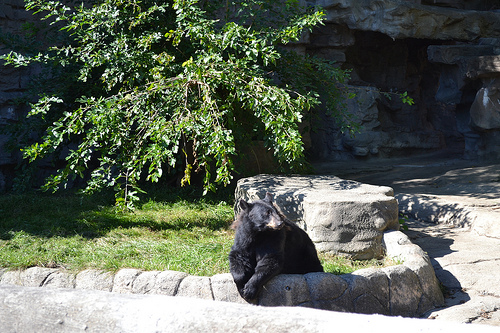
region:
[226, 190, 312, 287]
this is a bear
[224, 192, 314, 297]
the bear is sitted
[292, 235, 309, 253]
the fur is black in color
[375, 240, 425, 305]
this is a stony fence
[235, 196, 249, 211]
this is the ear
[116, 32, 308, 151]
the tree is branchy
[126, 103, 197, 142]
the leaves are green in color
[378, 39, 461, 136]
this is a cave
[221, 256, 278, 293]
these are the fore limbs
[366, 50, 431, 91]
the cave is dark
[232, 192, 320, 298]
black bear in grass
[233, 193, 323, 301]
black bear on rocks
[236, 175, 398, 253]
grey rock boulder on ground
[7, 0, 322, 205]
tree with green leaves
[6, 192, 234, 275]
grass next to tree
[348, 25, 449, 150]
cave inside rock wall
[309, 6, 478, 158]
stacked boulders on ground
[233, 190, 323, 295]
bear sitting on ground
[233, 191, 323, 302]
bear relaxing in sun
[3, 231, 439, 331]
concrete barrier on ground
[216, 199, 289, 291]
Bear leaning over a rock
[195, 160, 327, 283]
Black bear standing on rock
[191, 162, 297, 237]
Bear with his head turned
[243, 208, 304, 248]
Bear with brown and black nose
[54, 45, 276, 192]
Tree over a rock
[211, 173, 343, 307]
Bear hanging over a rock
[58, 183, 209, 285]
Patch of grass surrounded by stone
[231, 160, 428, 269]
Platform in the grass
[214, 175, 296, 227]
Bear with it's ears perked up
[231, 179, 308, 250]
Bear looking forward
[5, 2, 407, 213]
green leaves of bush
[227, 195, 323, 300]
bear leaning on wall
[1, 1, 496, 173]
wall of zoo enclosure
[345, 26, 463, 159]
opening in rock wall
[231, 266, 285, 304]
two front black paws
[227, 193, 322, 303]
black bear looking right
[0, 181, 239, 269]
green grass with shadows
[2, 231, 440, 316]
man made stone wall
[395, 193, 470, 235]
shadow of leaves on ground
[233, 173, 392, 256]
round flat top stone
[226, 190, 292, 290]
this is a bear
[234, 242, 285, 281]
the bear is black in color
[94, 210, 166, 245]
this is a grass area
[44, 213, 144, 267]
the grass is green in color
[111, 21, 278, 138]
this is a tree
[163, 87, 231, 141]
the leaves are green in color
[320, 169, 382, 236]
this is a rock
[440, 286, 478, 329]
this is the ground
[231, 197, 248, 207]
this is the ear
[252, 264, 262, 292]
this is the leg